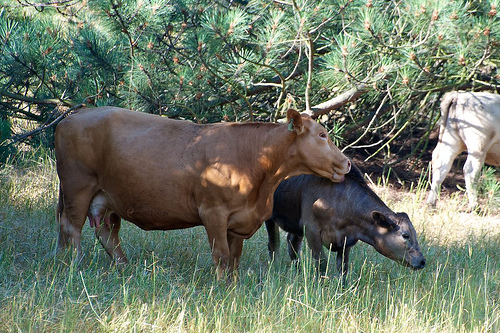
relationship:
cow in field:
[66, 80, 387, 287] [5, 154, 498, 307]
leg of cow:
[194, 193, 244, 261] [66, 80, 387, 287]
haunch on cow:
[234, 184, 280, 244] [66, 80, 387, 287]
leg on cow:
[194, 193, 244, 261] [66, 80, 387, 287]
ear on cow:
[286, 107, 303, 142] [66, 80, 387, 287]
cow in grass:
[66, 80, 387, 287] [4, 185, 459, 320]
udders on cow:
[86, 208, 116, 238] [66, 80, 387, 287]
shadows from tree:
[382, 183, 496, 314] [91, 1, 444, 116]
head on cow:
[288, 89, 349, 180] [66, 80, 387, 287]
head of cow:
[288, 89, 349, 180] [66, 80, 387, 287]